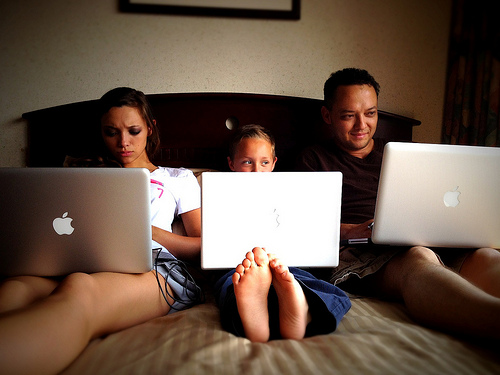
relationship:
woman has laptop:
[58, 82, 198, 311] [5, 164, 154, 281]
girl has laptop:
[202, 121, 333, 354] [194, 169, 347, 275]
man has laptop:
[311, 66, 495, 337] [368, 137, 498, 258]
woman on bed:
[58, 82, 198, 311] [17, 83, 487, 372]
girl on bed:
[202, 121, 333, 354] [17, 83, 487, 372]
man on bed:
[311, 66, 495, 337] [17, 83, 487, 372]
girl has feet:
[202, 121, 333, 354] [222, 245, 311, 348]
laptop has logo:
[5, 164, 154, 281] [52, 209, 76, 238]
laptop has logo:
[194, 169, 347, 275] [263, 206, 282, 230]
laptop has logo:
[368, 137, 498, 258] [438, 185, 462, 211]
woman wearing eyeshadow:
[58, 82, 198, 311] [128, 123, 143, 139]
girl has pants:
[202, 121, 333, 354] [209, 265, 353, 337]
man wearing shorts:
[311, 66, 495, 337] [333, 247, 393, 283]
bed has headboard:
[17, 83, 487, 372] [11, 87, 418, 143]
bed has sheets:
[17, 83, 487, 372] [110, 338, 461, 368]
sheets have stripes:
[110, 338, 461, 368] [151, 330, 222, 369]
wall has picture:
[13, 8, 448, 95] [115, 2, 304, 31]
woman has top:
[58, 82, 198, 311] [146, 159, 200, 243]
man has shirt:
[311, 66, 495, 337] [310, 146, 379, 218]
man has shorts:
[311, 66, 495, 337] [333, 247, 393, 283]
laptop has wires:
[5, 164, 154, 281] [151, 243, 202, 314]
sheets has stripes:
[110, 338, 461, 368] [151, 330, 222, 369]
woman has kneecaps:
[58, 82, 198, 311] [5, 266, 95, 299]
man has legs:
[311, 66, 495, 337] [390, 247, 496, 346]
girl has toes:
[202, 121, 333, 354] [226, 246, 299, 287]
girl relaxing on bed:
[202, 121, 333, 354] [17, 83, 487, 372]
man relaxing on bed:
[311, 66, 495, 337] [17, 83, 487, 372]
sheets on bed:
[110, 338, 461, 368] [17, 83, 487, 372]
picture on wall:
[115, 2, 304, 31] [13, 8, 448, 95]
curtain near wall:
[442, 5, 497, 145] [13, 8, 448, 95]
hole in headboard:
[221, 111, 240, 133] [11, 87, 418, 143]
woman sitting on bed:
[58, 82, 198, 311] [17, 83, 487, 372]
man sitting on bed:
[311, 66, 495, 337] [17, 83, 487, 372]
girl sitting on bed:
[202, 121, 333, 354] [17, 83, 487, 372]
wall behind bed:
[13, 8, 448, 95] [17, 83, 487, 372]